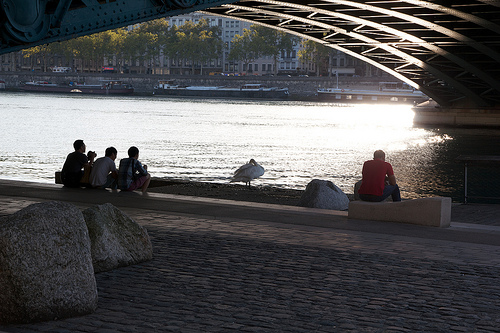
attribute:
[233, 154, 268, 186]
bird — white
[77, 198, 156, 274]
rock — big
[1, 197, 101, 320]
rock — big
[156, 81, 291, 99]
boat — large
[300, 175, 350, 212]
rock — gray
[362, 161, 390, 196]
shirt — red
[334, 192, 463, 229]
block — cement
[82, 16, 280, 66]
trees — green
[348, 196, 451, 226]
block — tan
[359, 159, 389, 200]
shirt — red